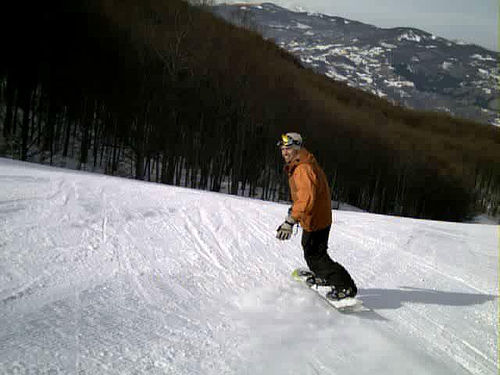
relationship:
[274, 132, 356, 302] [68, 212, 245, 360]
man snowboarding down slope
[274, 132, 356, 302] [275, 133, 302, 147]
man wearing ski goggles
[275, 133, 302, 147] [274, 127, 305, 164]
goggles on head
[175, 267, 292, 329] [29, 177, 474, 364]
tracks in snow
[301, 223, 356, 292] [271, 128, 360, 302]
black pants on boarder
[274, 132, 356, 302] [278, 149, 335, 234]
man wearing orange jacket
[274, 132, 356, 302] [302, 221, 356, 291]
man wearing black pants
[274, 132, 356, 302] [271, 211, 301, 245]
man wearing grey gloves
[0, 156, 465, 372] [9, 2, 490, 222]
patches on mountain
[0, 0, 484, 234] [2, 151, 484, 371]
trees on snow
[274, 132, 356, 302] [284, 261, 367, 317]
man on snowboard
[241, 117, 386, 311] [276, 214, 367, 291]
man wearing pants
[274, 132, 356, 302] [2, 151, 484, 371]
man enjoying snow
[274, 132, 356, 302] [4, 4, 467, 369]
man snowboarding down mountain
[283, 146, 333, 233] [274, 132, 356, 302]
jacket of man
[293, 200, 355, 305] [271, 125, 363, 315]
black pants of snowboarder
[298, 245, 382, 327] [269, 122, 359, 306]
snowboard of snowboarder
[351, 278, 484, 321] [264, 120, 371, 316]
shadow of snowboarder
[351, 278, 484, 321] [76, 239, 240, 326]
shadow on snow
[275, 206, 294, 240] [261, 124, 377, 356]
glove of snowboarder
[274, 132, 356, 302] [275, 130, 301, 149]
man wearing cap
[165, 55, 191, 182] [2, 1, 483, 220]
tree covering side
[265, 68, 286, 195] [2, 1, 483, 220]
tree covering side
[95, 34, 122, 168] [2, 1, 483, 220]
tree covering side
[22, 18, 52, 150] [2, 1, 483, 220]
tree covering side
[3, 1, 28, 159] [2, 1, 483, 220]
tree covering side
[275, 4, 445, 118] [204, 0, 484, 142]
patches on mountain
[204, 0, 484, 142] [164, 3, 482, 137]
mountain in background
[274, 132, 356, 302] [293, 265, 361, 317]
man on snowboard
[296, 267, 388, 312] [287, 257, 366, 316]
boot clipped into board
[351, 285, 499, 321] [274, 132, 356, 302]
shadow of man